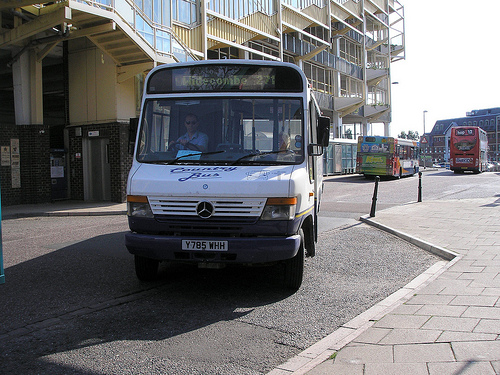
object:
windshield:
[134, 96, 305, 161]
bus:
[125, 48, 326, 295]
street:
[3, 151, 500, 374]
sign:
[192, 198, 214, 219]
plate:
[177, 233, 233, 255]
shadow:
[2, 229, 301, 372]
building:
[3, 1, 406, 203]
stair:
[46, 1, 206, 61]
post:
[420, 107, 431, 135]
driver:
[162, 108, 215, 153]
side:
[133, 98, 217, 160]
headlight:
[122, 193, 302, 224]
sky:
[366, 1, 500, 143]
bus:
[445, 120, 490, 174]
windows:
[170, 37, 188, 65]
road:
[0, 154, 500, 373]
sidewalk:
[272, 196, 500, 374]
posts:
[368, 174, 380, 216]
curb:
[281, 174, 500, 374]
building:
[425, 108, 500, 168]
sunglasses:
[181, 117, 202, 126]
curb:
[418, 160, 449, 167]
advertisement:
[453, 139, 478, 153]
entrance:
[76, 131, 118, 204]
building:
[4, 1, 123, 197]